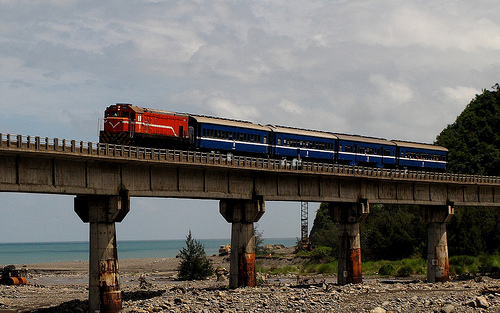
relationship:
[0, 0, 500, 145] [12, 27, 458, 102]
clouds in sky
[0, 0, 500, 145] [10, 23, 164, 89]
clouds in sky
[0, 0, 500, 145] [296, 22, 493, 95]
clouds in sky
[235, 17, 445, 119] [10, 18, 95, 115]
clouds in sky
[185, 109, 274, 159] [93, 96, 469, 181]
car of train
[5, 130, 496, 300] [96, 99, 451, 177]
bridge for train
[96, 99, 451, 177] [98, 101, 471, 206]
train on bridge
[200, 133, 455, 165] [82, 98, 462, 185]
stripe on train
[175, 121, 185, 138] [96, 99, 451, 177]
door to train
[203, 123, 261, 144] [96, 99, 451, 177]
windows of train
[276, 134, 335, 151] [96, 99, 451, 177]
windows of train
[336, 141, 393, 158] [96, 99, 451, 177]
windows of train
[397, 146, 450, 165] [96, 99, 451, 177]
windows of train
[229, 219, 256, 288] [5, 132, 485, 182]
pillar supporting railroad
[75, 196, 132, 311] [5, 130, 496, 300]
post for bridge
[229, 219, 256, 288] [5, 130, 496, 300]
pillar for bridge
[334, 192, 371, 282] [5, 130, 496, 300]
post for bridge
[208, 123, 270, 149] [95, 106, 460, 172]
windows on train